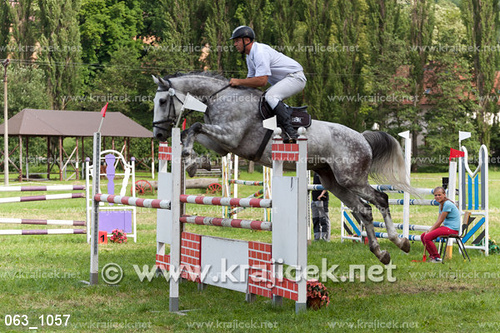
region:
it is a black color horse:
[151, 64, 418, 261]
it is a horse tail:
[363, 123, 419, 200]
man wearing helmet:
[227, 22, 257, 58]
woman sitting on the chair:
[418, 187, 474, 259]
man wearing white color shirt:
[229, 29, 312, 132]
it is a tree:
[386, 2, 453, 147]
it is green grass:
[376, 292, 498, 318]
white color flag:
[175, 86, 208, 134]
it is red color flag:
[96, 99, 113, 134]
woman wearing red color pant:
[419, 186, 461, 271]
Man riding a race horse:
[110, 8, 415, 318]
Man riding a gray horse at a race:
[161, 17, 423, 273]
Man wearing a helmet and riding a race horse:
[132, 12, 422, 279]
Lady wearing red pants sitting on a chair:
[407, 180, 478, 270]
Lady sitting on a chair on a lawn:
[406, 171, 474, 282]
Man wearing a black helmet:
[216, 18, 274, 63]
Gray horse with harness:
[125, 51, 225, 182]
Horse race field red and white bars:
[70, 165, 331, 320]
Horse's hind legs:
[355, 201, 421, 277]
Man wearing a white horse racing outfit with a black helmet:
[222, 11, 324, 151]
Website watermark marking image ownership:
[98, 256, 399, 286]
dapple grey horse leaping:
[145, 70, 410, 261]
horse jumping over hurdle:
[140, 67, 291, 227]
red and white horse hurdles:
[175, 186, 305, 308]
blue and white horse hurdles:
[361, 175, 426, 241]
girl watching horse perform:
[420, 180, 475, 265]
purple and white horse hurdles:
[0, 171, 90, 246]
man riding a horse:
[137, 20, 324, 167]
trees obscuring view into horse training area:
[315, 0, 490, 140]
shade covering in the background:
[2, 103, 159, 204]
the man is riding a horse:
[188, 15, 467, 296]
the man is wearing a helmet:
[212, 17, 299, 63]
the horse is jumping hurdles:
[113, 113, 441, 318]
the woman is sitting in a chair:
[417, 148, 475, 287]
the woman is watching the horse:
[372, 140, 499, 228]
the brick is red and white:
[121, 203, 358, 330]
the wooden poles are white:
[153, 130, 492, 319]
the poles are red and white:
[15, 159, 81, 276]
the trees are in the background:
[64, 14, 279, 151]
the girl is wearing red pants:
[412, 195, 454, 305]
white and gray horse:
[147, 73, 411, 266]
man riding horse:
[227, 26, 309, 145]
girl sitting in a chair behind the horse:
[420, 186, 461, 260]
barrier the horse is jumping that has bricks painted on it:
[150, 127, 307, 312]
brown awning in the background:
[2, 108, 152, 178]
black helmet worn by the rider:
[228, 23, 253, 50]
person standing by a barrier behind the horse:
[303, 168, 330, 240]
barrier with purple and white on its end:
[0, 148, 138, 243]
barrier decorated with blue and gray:
[341, 125, 489, 257]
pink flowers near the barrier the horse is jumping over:
[302, 279, 327, 308]